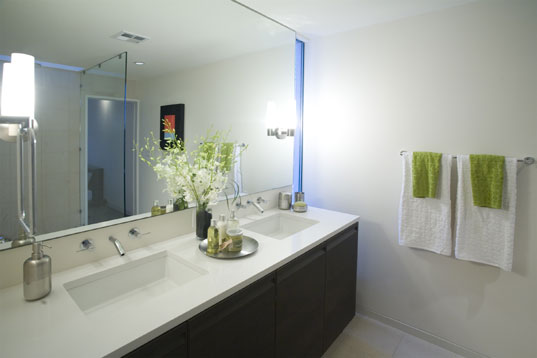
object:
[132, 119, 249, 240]
flower arrangement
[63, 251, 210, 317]
sink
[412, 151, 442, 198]
towel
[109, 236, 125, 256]
faucet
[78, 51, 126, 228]
divider